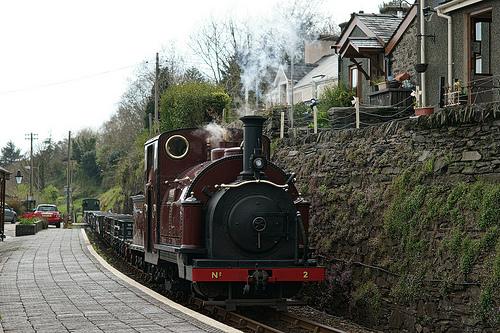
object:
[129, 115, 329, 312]
train engine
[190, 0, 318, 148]
smoke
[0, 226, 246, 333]
platform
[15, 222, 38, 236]
planters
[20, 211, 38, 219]
flowers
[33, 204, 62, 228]
car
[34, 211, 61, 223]
rear end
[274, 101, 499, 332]
wall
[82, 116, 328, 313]
train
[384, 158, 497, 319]
plants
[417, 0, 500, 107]
house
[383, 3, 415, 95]
house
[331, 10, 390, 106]
house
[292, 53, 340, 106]
house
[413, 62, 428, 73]
flower pot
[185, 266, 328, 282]
front bumper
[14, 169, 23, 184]
street light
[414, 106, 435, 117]
flower pot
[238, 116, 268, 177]
smoke stack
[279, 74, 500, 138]
fence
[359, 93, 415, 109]
wire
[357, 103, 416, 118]
wire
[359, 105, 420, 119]
wire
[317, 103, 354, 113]
wire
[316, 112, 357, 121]
wire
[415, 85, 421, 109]
post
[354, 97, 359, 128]
post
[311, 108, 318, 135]
post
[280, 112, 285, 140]
post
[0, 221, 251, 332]
road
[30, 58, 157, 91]
wire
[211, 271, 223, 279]
word no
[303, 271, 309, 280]
number 2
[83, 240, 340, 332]
train tracks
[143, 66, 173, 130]
tree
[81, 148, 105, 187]
tree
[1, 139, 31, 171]
tree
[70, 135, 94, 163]
tree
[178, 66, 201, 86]
tree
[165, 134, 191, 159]
window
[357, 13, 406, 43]
roof